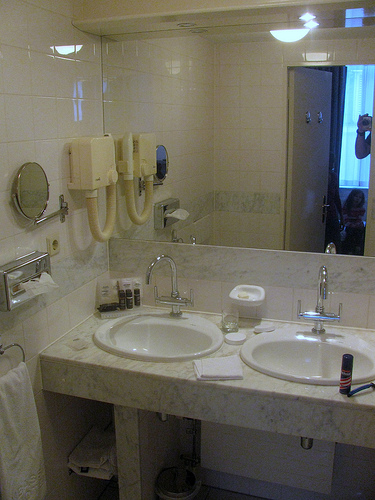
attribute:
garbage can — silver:
[154, 466, 201, 499]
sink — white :
[96, 304, 223, 358]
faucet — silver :
[140, 246, 195, 316]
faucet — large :
[144, 254, 190, 313]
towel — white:
[1, 360, 48, 498]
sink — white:
[90, 301, 224, 362]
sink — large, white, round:
[93, 307, 222, 364]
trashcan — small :
[148, 461, 207, 499]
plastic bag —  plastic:
[154, 463, 201, 498]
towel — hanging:
[6, 352, 62, 434]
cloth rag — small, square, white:
[189, 353, 246, 383]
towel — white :
[0, 342, 66, 493]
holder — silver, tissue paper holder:
[3, 248, 56, 310]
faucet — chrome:
[129, 255, 193, 326]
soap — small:
[215, 316, 275, 354]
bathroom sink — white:
[87, 303, 328, 364]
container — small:
[221, 318, 248, 344]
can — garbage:
[161, 462, 195, 481]